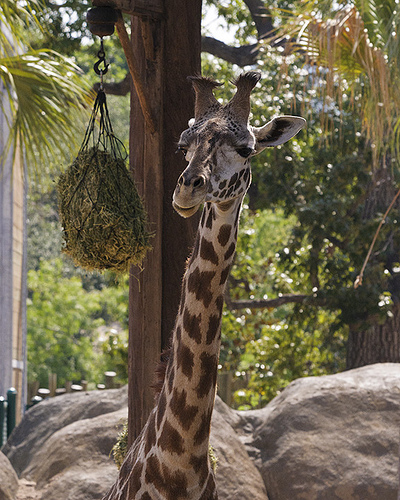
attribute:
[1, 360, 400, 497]
rocks — grey, big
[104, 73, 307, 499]
giraffe — spotted, standing, brown, white, along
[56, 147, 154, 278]
hay — hanging, bundled, green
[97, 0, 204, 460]
pole — wooden, long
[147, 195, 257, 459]
neck — long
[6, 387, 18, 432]
fence post — green, metal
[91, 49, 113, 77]
hook — black